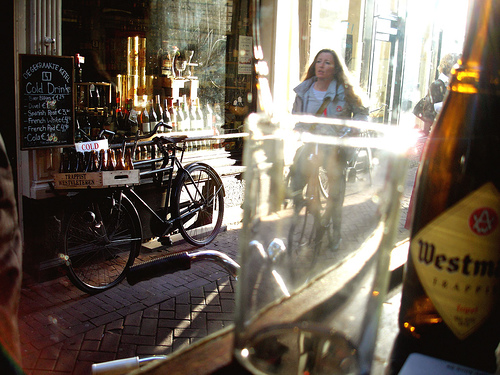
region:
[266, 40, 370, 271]
a woman standing in a store.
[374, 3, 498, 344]
a large brown bottle.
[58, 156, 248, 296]
A bike in a bar.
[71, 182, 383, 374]
a sidewalk outside of a building.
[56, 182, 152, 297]
a front bike tire.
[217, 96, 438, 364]
a large glass near a bottle.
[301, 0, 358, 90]
the side of a building.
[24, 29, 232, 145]
A bar in a room.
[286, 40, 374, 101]
a woman with long hair.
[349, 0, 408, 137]
an entrance into a building.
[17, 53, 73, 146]
Sign with chalk written words on it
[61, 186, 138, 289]
A front wheel on a bike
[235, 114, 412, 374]
A glass cup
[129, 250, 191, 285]
A left black handle on a bike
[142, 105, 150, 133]
A glass bottle in a window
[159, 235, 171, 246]
Pedal on a bike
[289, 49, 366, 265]
A woman on a bike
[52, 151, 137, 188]
A bottle basket on a bike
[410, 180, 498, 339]
A brand logo on a bottle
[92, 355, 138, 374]
A white handle on a bike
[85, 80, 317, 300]
a bike against a building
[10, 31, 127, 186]
a chalkboard outside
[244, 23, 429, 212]
a woman riding a bike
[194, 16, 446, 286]
a woman with long hiar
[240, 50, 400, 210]
a woman with long curly haiar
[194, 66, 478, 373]
a glass on a table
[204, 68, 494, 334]
a clear glass on a table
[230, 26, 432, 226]
a woman wearing a jacket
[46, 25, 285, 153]
a store front window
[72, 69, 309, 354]
a ike with bottles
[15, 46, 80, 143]
menu on black chalkboard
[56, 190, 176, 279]
front black wheel of bicycle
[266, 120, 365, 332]
clear glass in front of photo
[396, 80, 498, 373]
brown bottle with yellow label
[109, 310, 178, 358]
red brick road on ground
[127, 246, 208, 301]
black handle bar on bike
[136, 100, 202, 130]
long row of wine bottles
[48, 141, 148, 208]
wooden crate filled with bottles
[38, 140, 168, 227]
wooden crate on front of bike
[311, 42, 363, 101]
woman looking forward in photo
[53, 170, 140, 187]
short brown wooden crate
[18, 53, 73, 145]
black chalk board with brown frame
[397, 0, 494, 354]
brown glass beer bottle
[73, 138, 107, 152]
white sign that says COLD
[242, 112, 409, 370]
clear glass cup that is empty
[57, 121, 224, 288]
black bicycle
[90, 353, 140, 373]
white bike grip handle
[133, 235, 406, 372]
wooden bar on the right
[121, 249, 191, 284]
black bike handle on the right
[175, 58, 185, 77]
clear empty glass wine glass